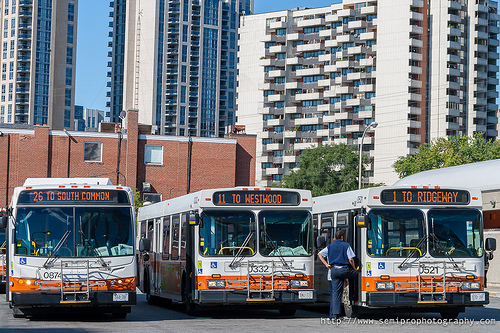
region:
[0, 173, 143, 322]
The bus with 26 on the digital board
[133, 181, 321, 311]
The bus with 11 on the digital board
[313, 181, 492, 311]
The bus with 1 on the digital board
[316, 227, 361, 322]
The man with his foot on a bus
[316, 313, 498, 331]
The website of the photographer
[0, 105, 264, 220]
The red brick building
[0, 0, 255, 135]
The two buildings that look similar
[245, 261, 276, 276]
The number 0332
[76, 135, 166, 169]
The windows in the brick building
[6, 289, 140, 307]
The bumper of the bus furthest to the left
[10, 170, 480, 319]
Three Buses in a row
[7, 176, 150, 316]
Bus #26 going to South Common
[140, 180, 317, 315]
Bus # 11 going to Westwood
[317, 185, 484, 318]
Bus # 1 going to Ridgeway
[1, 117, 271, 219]
Brick building behind buses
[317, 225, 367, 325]
Bus drivers standing next to buses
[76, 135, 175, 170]
Two window in Brick building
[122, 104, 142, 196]
Brick chimney on brick building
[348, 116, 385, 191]
Street light pole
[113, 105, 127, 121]
Satellite dish on brick building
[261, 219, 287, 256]
front window of a bus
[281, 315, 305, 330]
part of a road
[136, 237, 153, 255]
side mirror of a bus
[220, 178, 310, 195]
top of a bus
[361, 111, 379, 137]
part of a streetlight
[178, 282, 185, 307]
part of a front wheel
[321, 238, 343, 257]
part of a sweater top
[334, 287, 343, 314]
part of a blue trouser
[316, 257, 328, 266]
part of a left arm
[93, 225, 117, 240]
part of a steering wheel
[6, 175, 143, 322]
bus to South Common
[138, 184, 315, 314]
bus number 11 to Westwood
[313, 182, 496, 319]
bus 1 to Ridgeway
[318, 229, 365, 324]
man wearing a blue dress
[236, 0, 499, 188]
high rise apartment building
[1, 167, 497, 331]
Three city buses parked in a row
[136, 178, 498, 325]
two city buses parked together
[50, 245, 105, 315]
bike rack on front of a bus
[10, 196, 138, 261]
city bus front windshield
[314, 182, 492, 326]
bus driver with one foot on the bus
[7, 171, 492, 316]
three parked buses ready to go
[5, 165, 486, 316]
the buses are white with an orange stripe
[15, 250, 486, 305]
bike racks are on the front of the buses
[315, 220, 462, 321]
a man is talking to the bus driver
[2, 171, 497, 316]
the buses are in a parking lot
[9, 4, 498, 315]
tall buildings are around the buses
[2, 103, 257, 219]
red brick building is behind the buses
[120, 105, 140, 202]
a chimney is on the building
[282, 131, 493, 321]
trees are growing near the buses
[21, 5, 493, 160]
the sky is blue between the buildings